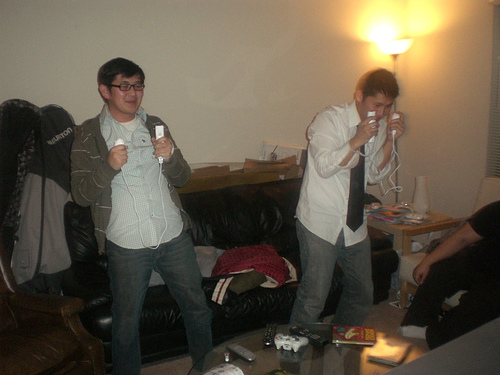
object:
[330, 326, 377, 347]
book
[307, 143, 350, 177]
elbows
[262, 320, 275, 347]
black remote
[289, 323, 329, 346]
black remote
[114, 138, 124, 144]
controller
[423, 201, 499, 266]
arm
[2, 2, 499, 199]
walls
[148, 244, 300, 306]
clothing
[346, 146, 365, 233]
tie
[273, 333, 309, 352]
controller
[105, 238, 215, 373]
jeans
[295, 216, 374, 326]
jeans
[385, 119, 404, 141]
man's hand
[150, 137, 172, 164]
man's hand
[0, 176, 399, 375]
couch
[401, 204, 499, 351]
man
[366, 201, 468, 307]
table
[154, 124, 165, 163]
controls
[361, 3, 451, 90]
lamp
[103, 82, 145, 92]
glasses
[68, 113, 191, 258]
jacket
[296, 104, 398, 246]
shirt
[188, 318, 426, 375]
table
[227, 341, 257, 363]
cellphone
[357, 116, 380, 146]
hands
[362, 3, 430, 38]
top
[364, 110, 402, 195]
game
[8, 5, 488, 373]
room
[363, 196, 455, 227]
surface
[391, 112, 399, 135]
controls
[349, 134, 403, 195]
chest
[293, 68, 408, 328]
man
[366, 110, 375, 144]
controls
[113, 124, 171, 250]
game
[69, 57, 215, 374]
he